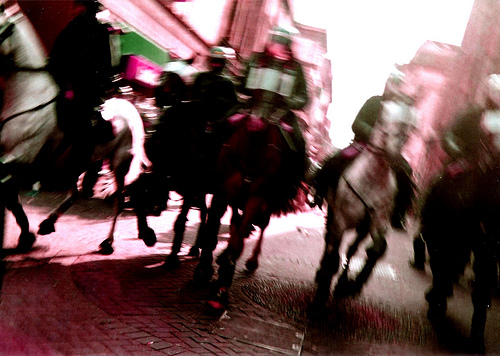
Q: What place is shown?
A: It is a road.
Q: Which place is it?
A: It is a road.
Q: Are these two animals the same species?
A: Yes, all the animals are horses.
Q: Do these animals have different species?
A: No, all the animals are horses.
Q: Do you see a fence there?
A: No, there are no fences.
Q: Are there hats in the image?
A: Yes, there is a hat.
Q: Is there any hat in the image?
A: Yes, there is a hat.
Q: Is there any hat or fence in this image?
A: Yes, there is a hat.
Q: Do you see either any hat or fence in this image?
A: Yes, there is a hat.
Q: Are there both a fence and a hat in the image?
A: No, there is a hat but no fences.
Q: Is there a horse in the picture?
A: Yes, there is a horse.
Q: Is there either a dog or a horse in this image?
A: Yes, there is a horse.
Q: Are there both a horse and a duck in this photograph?
A: No, there is a horse but no ducks.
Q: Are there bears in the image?
A: No, there are no bears.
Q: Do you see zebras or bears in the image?
A: No, there are no bears or zebras.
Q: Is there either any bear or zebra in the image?
A: No, there are no bears or zebras.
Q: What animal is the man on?
A: The man is on the horse.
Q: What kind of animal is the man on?
A: The man is on the horse.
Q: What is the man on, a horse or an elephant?
A: The man is on a horse.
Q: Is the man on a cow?
A: No, the man is on the horse.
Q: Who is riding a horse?
A: The man is riding a horse.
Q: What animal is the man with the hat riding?
A: The man is riding a horse.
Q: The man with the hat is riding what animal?
A: The man is riding a horse.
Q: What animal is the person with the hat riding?
A: The man is riding a horse.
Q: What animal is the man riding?
A: The man is riding a horse.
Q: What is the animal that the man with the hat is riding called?
A: The animal is a horse.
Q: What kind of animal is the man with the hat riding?
A: The man is riding a horse.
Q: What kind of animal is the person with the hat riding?
A: The man is riding a horse.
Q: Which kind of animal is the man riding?
A: The man is riding a horse.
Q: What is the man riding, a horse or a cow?
A: The man is riding a horse.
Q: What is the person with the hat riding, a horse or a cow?
A: The man is riding a horse.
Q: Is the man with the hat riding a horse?
A: Yes, the man is riding a horse.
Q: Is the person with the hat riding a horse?
A: Yes, the man is riding a horse.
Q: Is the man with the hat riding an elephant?
A: No, the man is riding a horse.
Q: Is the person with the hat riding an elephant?
A: No, the man is riding a horse.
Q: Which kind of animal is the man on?
A: The man is on the horse.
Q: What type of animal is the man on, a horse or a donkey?
A: The man is on a horse.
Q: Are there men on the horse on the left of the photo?
A: Yes, there is a man on the horse.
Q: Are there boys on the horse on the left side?
A: No, there is a man on the horse.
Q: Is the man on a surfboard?
A: No, the man is on the horse.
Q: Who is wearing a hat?
A: The man is wearing a hat.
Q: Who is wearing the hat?
A: The man is wearing a hat.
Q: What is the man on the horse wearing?
A: The man is wearing a hat.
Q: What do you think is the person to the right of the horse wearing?
A: The man is wearing a hat.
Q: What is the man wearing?
A: The man is wearing a hat.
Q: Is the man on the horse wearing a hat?
A: Yes, the man is wearing a hat.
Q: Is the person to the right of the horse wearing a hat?
A: Yes, the man is wearing a hat.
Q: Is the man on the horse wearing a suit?
A: No, the man is wearing a hat.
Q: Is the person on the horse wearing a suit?
A: No, the man is wearing a hat.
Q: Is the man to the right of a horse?
A: Yes, the man is to the right of a horse.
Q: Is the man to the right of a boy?
A: No, the man is to the right of a horse.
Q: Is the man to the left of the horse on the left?
A: No, the man is to the right of the horse.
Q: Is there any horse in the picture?
A: Yes, there is a horse.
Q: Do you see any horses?
A: Yes, there is a horse.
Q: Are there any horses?
A: Yes, there is a horse.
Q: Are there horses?
A: Yes, there is a horse.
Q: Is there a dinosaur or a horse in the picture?
A: Yes, there is a horse.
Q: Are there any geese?
A: No, there are no geese.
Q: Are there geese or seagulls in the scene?
A: No, there are no geese or seagulls.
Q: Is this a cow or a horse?
A: This is a horse.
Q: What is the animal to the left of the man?
A: The animal is a horse.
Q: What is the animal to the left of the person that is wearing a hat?
A: The animal is a horse.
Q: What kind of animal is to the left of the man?
A: The animal is a horse.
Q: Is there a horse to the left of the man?
A: Yes, there is a horse to the left of the man.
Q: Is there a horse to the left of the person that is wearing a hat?
A: Yes, there is a horse to the left of the man.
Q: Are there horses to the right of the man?
A: No, the horse is to the left of the man.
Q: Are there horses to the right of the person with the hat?
A: No, the horse is to the left of the man.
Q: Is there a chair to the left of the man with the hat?
A: No, there is a horse to the left of the man.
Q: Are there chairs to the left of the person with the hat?
A: No, there is a horse to the left of the man.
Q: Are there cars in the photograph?
A: No, there are no cars.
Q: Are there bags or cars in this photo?
A: No, there are no cars or bags.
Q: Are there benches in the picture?
A: No, there are no benches.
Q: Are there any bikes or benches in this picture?
A: No, there are no benches or bikes.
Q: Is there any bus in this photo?
A: No, there are no buses.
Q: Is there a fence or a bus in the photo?
A: No, there are no buses or fences.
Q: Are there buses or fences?
A: No, there are no buses or fences.